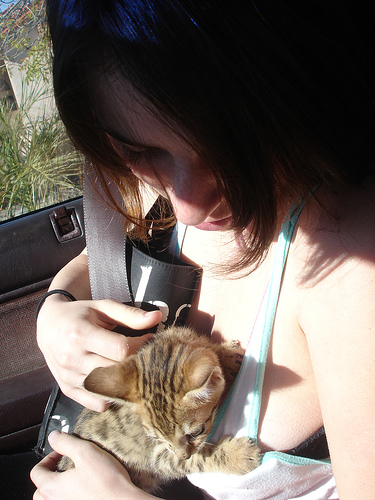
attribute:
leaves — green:
[19, 79, 25, 129]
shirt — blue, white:
[87, 178, 311, 376]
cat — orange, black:
[59, 324, 260, 491]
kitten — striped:
[55, 295, 244, 493]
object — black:
[110, 238, 205, 323]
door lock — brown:
[47, 203, 85, 243]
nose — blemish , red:
[154, 172, 223, 224]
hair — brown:
[41, 1, 374, 283]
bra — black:
[279, 421, 338, 462]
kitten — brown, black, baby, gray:
[62, 320, 264, 491]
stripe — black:
[142, 338, 190, 438]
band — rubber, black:
[41, 289, 75, 303]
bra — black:
[283, 423, 334, 459]